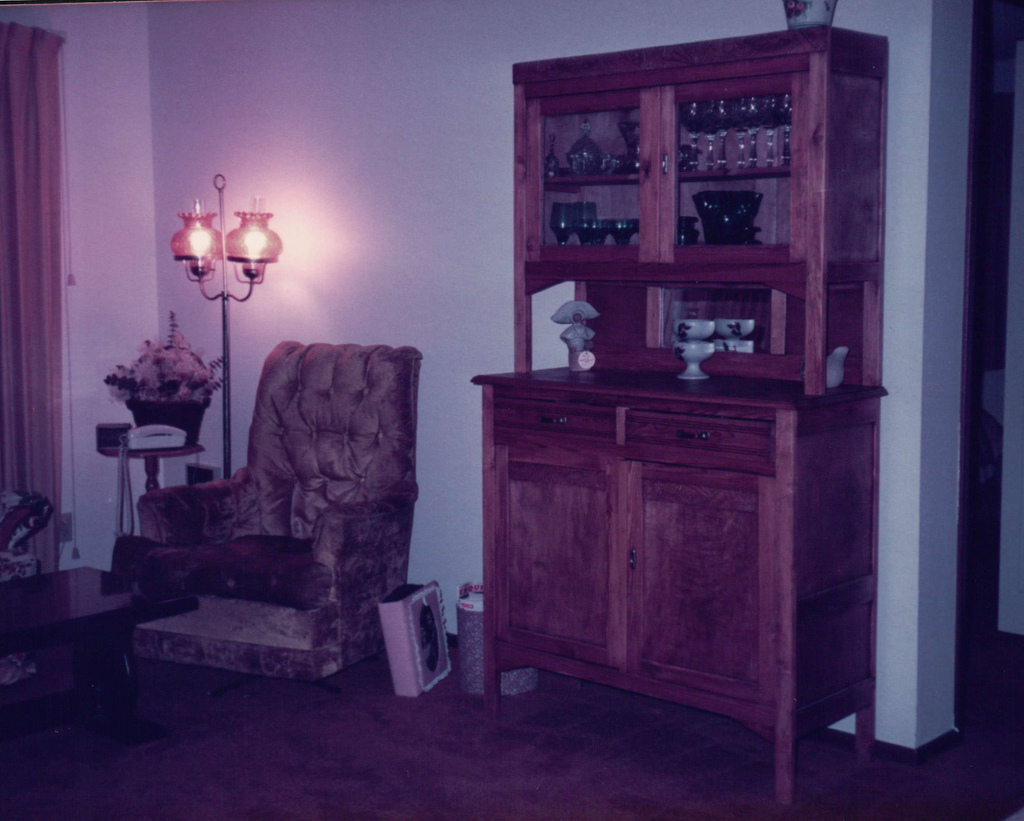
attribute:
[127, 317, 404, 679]
recliner — gold, velvet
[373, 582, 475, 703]
book — thick, white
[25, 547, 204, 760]
coffee table — brown, wooden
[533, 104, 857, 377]
cabinet — wooden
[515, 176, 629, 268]
cabinet — wooden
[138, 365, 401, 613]
chair — colored, tan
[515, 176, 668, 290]
glass — green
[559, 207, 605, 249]
glass — green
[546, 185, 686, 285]
glass — green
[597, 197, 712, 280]
glass — green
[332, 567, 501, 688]
album — fabric, covered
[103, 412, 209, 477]
phone — white, land line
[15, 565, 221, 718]
table — shiny, dark, brown, wood, coffee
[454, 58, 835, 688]
hutch — large, wooden, display hutch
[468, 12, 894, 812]
cabinet — wooden